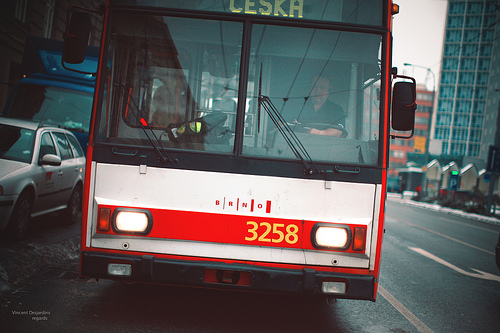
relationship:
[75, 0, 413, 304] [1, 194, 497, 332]
bus on street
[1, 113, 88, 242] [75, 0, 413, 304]
car next to bus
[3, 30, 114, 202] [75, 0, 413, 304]
truck next to bus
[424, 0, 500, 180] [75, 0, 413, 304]
buildings next to bus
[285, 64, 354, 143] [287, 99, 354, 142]
man in shirt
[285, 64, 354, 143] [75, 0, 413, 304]
man driving bus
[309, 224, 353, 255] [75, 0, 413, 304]
headlights on bus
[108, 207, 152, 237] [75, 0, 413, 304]
headlights on bus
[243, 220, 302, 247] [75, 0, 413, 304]
numbers on bus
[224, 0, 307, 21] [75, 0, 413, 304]
sign on bus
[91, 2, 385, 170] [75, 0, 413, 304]
windshield on bus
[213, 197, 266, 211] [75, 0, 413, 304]
letters on bus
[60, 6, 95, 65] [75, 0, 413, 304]
mirror on bus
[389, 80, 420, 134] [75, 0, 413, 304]
mirror on bus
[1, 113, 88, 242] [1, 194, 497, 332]
car on street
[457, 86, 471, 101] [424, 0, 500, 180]
window on buildings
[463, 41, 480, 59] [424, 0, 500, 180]
window on buildings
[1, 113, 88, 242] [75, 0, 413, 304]
car by bus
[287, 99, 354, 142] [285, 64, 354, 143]
shirt of man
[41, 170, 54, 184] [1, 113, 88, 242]
decal on car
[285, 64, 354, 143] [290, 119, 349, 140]
man behind wheel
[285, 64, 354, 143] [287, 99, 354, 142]
man wearing shirt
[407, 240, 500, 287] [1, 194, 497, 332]
marking on street